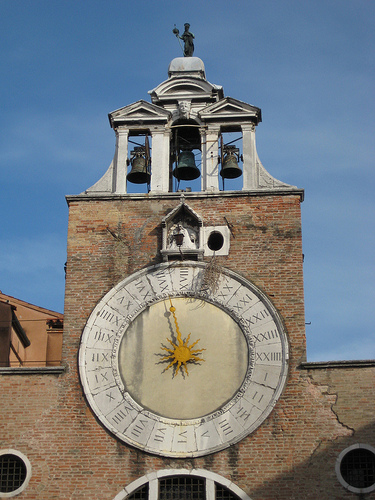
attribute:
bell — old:
[124, 146, 152, 184]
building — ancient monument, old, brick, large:
[3, 20, 375, 499]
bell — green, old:
[173, 145, 199, 179]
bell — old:
[220, 144, 244, 176]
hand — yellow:
[163, 287, 205, 379]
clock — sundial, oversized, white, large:
[75, 259, 292, 459]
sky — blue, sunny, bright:
[1, 0, 372, 364]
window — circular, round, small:
[334, 445, 373, 495]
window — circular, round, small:
[0, 448, 34, 498]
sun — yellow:
[155, 330, 207, 380]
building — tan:
[1, 287, 66, 366]